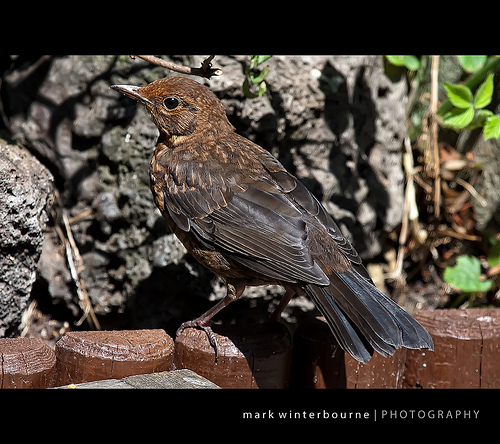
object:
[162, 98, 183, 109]
eye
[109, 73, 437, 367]
bird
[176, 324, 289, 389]
pole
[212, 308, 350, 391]
shade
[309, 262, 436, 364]
tail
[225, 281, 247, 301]
knee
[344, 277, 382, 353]
feather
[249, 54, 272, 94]
leaf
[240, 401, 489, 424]
graphic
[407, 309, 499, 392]
poles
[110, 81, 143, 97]
beak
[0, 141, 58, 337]
rocks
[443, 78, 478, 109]
leaves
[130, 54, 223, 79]
branch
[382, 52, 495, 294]
bush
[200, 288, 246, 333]
leg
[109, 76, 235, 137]
head